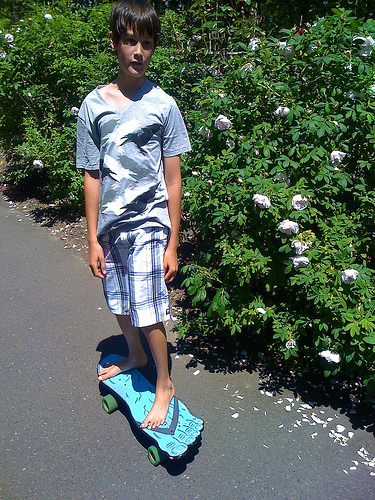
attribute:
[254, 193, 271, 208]
flowers — white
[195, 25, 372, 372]
bush — green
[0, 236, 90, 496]
ground — paved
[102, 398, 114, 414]
wheel — green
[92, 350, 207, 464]
skateboard — green, blue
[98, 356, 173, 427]
feet — bare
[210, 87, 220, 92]
flower — red, white, pink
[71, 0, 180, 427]
boy — barefoot, skateboarding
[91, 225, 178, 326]
shorts — plaid, white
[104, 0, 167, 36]
hair — black, brown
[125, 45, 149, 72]
facial expression — cool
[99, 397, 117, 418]
wheels — green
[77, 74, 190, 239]
shirt — blue, gray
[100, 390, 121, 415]
tire — green